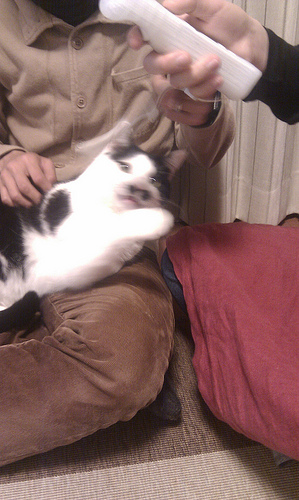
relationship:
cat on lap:
[4, 122, 179, 328] [2, 183, 173, 423]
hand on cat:
[1, 146, 58, 208] [4, 122, 179, 328]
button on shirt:
[72, 38, 83, 48] [0, 1, 234, 267]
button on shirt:
[74, 95, 85, 107] [0, 1, 234, 267]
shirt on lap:
[163, 216, 297, 458] [0, 218, 205, 466]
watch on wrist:
[198, 84, 229, 132] [188, 83, 227, 132]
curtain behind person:
[214, 96, 297, 242] [1, 1, 235, 464]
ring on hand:
[167, 91, 185, 113] [113, 12, 281, 100]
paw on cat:
[116, 205, 173, 244] [4, 122, 179, 328]